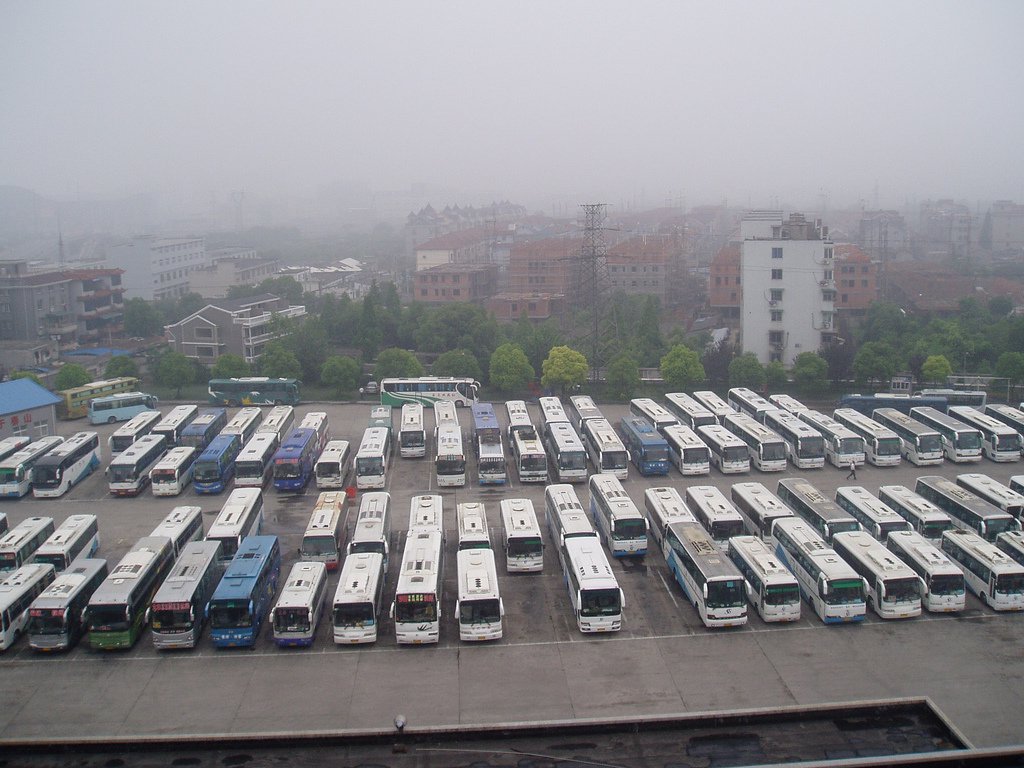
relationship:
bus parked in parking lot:
[455, 544, 508, 648] [1, 397, 1023, 761]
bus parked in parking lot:
[558, 526, 630, 637] [1, 397, 1023, 761]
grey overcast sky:
[30, 205, 994, 223] [45, 123, 1022, 262]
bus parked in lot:
[200, 526, 287, 645] [12, 402, 1019, 746]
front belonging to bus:
[204, 597, 257, 649] [197, 528, 284, 650]